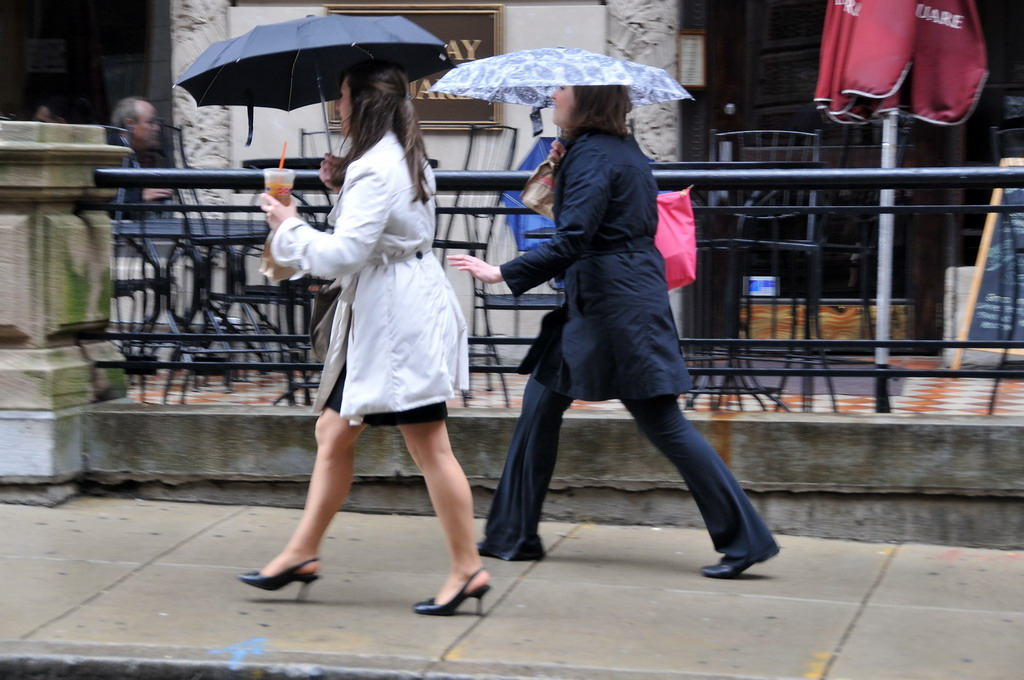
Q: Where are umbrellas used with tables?
A: On the shop patio.